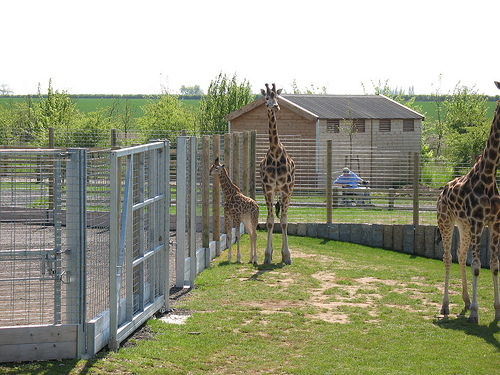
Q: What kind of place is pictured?
A: It is a field.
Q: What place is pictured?
A: It is a field.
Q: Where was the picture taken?
A: It was taken at the field.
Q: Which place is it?
A: It is a field.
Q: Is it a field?
A: Yes, it is a field.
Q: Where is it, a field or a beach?
A: It is a field.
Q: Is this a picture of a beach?
A: No, the picture is showing a field.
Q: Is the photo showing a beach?
A: No, the picture is showing a field.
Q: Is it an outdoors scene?
A: Yes, it is outdoors.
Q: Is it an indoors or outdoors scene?
A: It is outdoors.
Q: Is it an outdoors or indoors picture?
A: It is outdoors.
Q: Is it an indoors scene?
A: No, it is outdoors.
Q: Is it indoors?
A: No, it is outdoors.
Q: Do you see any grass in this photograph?
A: Yes, there is grass.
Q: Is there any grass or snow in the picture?
A: Yes, there is grass.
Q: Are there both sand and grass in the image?
A: No, there is grass but no sand.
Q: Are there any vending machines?
A: No, there are no vending machines.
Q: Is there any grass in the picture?
A: Yes, there is grass.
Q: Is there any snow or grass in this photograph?
A: Yes, there is grass.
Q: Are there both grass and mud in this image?
A: No, there is grass but no mud.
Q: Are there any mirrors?
A: No, there are no mirrors.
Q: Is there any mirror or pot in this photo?
A: No, there are no mirrors or pots.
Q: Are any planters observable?
A: No, there are no planters.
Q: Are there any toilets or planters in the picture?
A: No, there are no planters or toilets.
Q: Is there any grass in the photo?
A: Yes, there is grass.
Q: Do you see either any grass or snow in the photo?
A: Yes, there is grass.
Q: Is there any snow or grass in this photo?
A: Yes, there is grass.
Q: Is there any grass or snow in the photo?
A: Yes, there is grass.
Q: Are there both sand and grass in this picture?
A: No, there is grass but no sand.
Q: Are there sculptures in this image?
A: No, there are no sculptures.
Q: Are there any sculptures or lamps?
A: No, there are no sculptures or lamps.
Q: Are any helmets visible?
A: No, there are no helmets.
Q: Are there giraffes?
A: Yes, there is a giraffe.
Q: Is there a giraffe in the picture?
A: Yes, there is a giraffe.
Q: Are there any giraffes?
A: Yes, there is a giraffe.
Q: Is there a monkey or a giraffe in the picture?
A: Yes, there is a giraffe.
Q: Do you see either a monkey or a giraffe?
A: Yes, there is a giraffe.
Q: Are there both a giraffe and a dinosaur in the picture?
A: No, there is a giraffe but no dinosaurs.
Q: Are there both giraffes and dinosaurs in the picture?
A: No, there is a giraffe but no dinosaurs.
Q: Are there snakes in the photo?
A: No, there are no snakes.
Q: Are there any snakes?
A: No, there are no snakes.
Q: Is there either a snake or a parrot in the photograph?
A: No, there are no snakes or parrots.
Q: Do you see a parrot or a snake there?
A: No, there are no snakes or parrots.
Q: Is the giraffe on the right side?
A: Yes, the giraffe is on the right of the image.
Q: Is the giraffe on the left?
A: No, the giraffe is on the right of the image.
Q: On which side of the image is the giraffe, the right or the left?
A: The giraffe is on the right of the image.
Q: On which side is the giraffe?
A: The giraffe is on the right of the image.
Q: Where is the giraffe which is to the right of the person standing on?
A: The giraffe is standing on the grass.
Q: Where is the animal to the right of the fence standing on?
A: The giraffe is standing on the grass.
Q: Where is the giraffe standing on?
A: The giraffe is standing on the grass.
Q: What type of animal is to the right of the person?
A: The animal is a giraffe.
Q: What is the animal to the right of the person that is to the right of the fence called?
A: The animal is a giraffe.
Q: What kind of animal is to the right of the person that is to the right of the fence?
A: The animal is a giraffe.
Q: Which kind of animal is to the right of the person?
A: The animal is a giraffe.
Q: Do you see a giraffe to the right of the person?
A: Yes, there is a giraffe to the right of the person.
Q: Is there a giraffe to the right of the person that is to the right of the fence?
A: Yes, there is a giraffe to the right of the person.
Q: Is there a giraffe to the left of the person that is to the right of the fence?
A: No, the giraffe is to the right of the person.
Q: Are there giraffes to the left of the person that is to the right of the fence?
A: No, the giraffe is to the right of the person.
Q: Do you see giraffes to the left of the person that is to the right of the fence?
A: No, the giraffe is to the right of the person.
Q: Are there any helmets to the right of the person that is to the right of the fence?
A: No, there is a giraffe to the right of the person.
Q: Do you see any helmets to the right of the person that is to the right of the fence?
A: No, there is a giraffe to the right of the person.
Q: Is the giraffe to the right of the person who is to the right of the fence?
A: Yes, the giraffe is to the right of the person.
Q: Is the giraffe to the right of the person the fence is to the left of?
A: Yes, the giraffe is to the right of the person.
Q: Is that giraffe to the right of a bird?
A: No, the giraffe is to the right of the person.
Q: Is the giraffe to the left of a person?
A: No, the giraffe is to the right of a person.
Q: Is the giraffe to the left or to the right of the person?
A: The giraffe is to the right of the person.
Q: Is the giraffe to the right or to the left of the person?
A: The giraffe is to the right of the person.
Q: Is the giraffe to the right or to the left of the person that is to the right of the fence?
A: The giraffe is to the right of the person.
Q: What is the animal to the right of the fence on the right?
A: The animal is a giraffe.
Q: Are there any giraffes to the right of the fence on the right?
A: Yes, there is a giraffe to the right of the fence.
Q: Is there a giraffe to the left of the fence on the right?
A: No, the giraffe is to the right of the fence.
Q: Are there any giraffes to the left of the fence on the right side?
A: No, the giraffe is to the right of the fence.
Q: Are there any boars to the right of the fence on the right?
A: No, there is a giraffe to the right of the fence.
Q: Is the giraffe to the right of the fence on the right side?
A: Yes, the giraffe is to the right of the fence.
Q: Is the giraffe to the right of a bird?
A: No, the giraffe is to the right of the fence.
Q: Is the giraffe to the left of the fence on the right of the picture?
A: No, the giraffe is to the right of the fence.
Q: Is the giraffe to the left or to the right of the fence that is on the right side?
A: The giraffe is to the right of the fence.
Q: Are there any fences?
A: Yes, there is a fence.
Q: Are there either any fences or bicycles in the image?
A: Yes, there is a fence.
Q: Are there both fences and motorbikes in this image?
A: No, there is a fence but no motorcycles.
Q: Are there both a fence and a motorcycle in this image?
A: No, there is a fence but no motorcycles.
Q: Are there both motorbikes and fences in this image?
A: No, there is a fence but no motorcycles.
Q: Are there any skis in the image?
A: No, there are no skis.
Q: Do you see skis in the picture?
A: No, there are no skis.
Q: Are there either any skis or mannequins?
A: No, there are no skis or mannequins.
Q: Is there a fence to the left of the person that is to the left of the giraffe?
A: Yes, there is a fence to the left of the person.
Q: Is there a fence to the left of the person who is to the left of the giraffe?
A: Yes, there is a fence to the left of the person.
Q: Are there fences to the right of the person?
A: No, the fence is to the left of the person.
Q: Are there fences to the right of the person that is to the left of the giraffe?
A: No, the fence is to the left of the person.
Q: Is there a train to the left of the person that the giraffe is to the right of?
A: No, there is a fence to the left of the person.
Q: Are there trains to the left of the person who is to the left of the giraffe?
A: No, there is a fence to the left of the person.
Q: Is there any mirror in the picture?
A: No, there are no mirrors.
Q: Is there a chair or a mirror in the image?
A: No, there are no mirrors or chairs.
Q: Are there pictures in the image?
A: No, there are no pictures.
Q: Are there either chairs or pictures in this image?
A: No, there are no pictures or chairs.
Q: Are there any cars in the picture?
A: No, there are no cars.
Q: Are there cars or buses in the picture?
A: No, there are no cars or buses.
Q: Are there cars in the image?
A: No, there are no cars.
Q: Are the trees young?
A: Yes, the trees are young.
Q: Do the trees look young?
A: Yes, the trees are young.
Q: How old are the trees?
A: The trees are young.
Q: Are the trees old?
A: No, the trees are young.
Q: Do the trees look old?
A: No, the trees are young.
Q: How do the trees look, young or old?
A: The trees are young.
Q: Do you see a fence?
A: Yes, there is a fence.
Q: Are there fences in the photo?
A: Yes, there is a fence.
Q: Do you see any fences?
A: Yes, there is a fence.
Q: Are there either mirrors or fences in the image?
A: Yes, there is a fence.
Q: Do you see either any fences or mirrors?
A: Yes, there is a fence.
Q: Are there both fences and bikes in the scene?
A: No, there is a fence but no bikes.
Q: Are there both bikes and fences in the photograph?
A: No, there is a fence but no bikes.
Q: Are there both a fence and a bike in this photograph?
A: No, there is a fence but no bikes.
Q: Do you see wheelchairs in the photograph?
A: No, there are no wheelchairs.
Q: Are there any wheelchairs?
A: No, there are no wheelchairs.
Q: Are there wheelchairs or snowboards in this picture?
A: No, there are no wheelchairs or snowboards.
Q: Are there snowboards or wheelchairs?
A: No, there are no wheelchairs or snowboards.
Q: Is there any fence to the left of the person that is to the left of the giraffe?
A: Yes, there is a fence to the left of the person.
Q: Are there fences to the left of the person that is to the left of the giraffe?
A: Yes, there is a fence to the left of the person.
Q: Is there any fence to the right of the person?
A: No, the fence is to the left of the person.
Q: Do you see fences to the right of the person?
A: No, the fence is to the left of the person.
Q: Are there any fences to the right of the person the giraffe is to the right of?
A: No, the fence is to the left of the person.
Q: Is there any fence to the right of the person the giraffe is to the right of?
A: No, the fence is to the left of the person.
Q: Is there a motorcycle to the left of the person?
A: No, there is a fence to the left of the person.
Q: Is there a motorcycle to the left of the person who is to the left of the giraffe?
A: No, there is a fence to the left of the person.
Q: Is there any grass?
A: Yes, there is grass.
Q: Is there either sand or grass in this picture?
A: Yes, there is grass.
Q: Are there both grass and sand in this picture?
A: No, there is grass but no sand.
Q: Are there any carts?
A: No, there are no carts.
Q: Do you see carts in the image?
A: No, there are no carts.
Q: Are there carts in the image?
A: No, there are no carts.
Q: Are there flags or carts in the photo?
A: No, there are no carts or flags.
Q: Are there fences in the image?
A: Yes, there is a fence.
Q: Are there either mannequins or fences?
A: Yes, there is a fence.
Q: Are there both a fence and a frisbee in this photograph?
A: No, there is a fence but no frisbees.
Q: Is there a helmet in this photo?
A: No, there are no helmets.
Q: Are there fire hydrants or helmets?
A: No, there are no helmets or fire hydrants.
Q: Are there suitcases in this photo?
A: No, there are no suitcases.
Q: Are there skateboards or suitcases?
A: No, there are no suitcases or skateboards.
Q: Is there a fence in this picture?
A: Yes, there is a fence.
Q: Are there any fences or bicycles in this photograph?
A: Yes, there is a fence.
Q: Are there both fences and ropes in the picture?
A: No, there is a fence but no ropes.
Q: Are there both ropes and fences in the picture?
A: No, there is a fence but no ropes.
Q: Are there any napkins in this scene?
A: No, there are no napkins.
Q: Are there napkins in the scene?
A: No, there are no napkins.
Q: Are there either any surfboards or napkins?
A: No, there are no napkins or surfboards.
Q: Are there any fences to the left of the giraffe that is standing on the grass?
A: Yes, there is a fence to the left of the giraffe.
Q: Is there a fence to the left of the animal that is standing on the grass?
A: Yes, there is a fence to the left of the giraffe.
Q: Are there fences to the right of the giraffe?
A: No, the fence is to the left of the giraffe.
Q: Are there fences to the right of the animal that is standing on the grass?
A: No, the fence is to the left of the giraffe.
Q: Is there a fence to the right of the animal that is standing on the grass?
A: No, the fence is to the left of the giraffe.